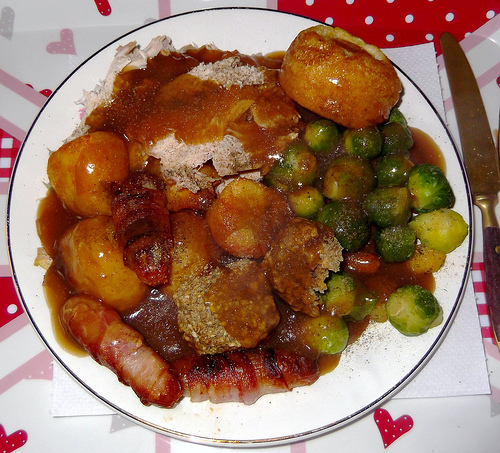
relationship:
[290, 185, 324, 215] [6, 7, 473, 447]
brussel sprout on plate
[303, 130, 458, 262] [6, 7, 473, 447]
veggie on plate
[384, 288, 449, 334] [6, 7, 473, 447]
sprout on plate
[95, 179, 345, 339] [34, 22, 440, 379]
food on plate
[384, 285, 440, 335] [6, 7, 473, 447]
sprout on plate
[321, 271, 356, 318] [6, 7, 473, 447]
green veggie on plate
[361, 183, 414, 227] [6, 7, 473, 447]
vegetable on plate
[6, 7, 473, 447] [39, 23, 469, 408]
plate with food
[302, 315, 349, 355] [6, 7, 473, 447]
veggie on plate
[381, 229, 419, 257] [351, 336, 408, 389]
veggie on plate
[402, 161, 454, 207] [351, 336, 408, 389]
veggie on plate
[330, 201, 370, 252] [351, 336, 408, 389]
veggie on plate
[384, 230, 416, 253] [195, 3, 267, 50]
brussel on plate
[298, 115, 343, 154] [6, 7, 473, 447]
veggie on a plate